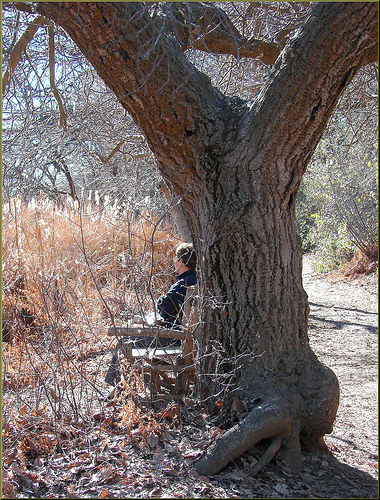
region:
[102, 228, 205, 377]
lady sitting on the bench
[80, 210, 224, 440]
lady sitting on the bench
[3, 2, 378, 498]
a scene outside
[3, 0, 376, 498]
a scene during the day time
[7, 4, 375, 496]
a scene in the woods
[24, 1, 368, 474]
a large tree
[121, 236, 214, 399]
a person sitting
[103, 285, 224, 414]
a wooden bench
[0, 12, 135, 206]
a blue sky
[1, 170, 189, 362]
some brown brush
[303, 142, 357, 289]
a green bush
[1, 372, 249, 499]
few brown leaves on the ground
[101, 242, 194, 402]
person sitting on a bench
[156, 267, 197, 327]
person wearing a blue jacket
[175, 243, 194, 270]
person has short brown hair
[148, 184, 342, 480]
person sitting beside tree trunk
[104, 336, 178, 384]
person wearing gray pants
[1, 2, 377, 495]
the season of the year is fall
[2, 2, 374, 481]
the tree is bare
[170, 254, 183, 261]
person is wearing eye glasses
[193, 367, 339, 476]
roots are coming out of the ground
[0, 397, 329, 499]
leaves on the ground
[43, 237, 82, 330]
dead grass on ground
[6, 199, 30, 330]
dead grass on ground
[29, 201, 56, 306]
dead grass on ground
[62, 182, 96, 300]
dead grass on ground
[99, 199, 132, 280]
dead grass on ground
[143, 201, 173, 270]
dead grass on ground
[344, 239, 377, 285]
dead grass on ground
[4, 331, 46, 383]
dead grass on ground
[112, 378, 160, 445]
dead grass on ground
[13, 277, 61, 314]
dead grass on ground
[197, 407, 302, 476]
two large tree roots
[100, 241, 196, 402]
a man sitting on a bench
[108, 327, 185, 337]
the left wooden arm of a bench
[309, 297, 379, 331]
the shadow of tree limbs on the ground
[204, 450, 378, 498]
the tree's shadow on the ground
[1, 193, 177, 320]
tall wheat in a field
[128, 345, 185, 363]
the seat of a bench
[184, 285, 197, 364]
the back of a wooden bench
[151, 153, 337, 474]
the wide trunk of an old tree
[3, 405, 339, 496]
piles of dead tree leaves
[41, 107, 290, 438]
person sitting next to a tree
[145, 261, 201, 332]
person wearing a blue shirt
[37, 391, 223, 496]
multiple leafs on the ground